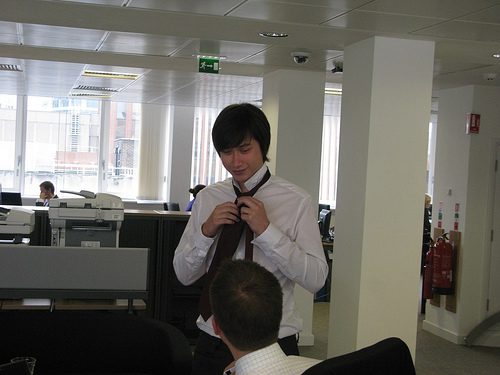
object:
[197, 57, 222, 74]
directional sign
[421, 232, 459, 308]
fire hydrant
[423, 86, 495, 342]
wall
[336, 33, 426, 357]
structure beam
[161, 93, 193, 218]
structure beam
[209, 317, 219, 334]
ear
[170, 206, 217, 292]
arm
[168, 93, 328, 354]
person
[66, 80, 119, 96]
vent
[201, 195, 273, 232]
hand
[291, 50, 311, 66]
security camera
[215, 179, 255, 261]
necktie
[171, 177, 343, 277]
shirt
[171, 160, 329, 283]
white shirt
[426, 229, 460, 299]
fire extinguisher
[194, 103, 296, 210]
eye person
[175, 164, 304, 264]
dress shirt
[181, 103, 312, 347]
man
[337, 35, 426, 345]
column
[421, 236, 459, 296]
extinguisher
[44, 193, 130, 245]
copy machine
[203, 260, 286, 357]
head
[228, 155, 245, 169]
nose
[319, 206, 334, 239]
computer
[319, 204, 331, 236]
monitor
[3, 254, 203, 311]
partition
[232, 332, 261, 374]
neck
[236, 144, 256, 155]
eye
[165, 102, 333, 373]
person